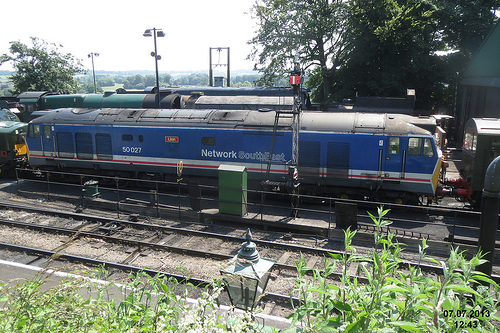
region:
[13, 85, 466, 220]
trains on the tracks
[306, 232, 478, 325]
green leaves on a tree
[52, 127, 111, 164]
windows of a train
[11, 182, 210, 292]
tracks of a train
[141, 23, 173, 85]
lights above a train station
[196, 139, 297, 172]
name of train on side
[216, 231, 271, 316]
lamp light by the tracks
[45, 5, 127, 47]
hazy sky in the distance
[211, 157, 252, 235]
electric box on the tracks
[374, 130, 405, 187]
door of a train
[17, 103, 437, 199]
a blue train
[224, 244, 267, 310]
a lamp post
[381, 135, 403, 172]
a door on the train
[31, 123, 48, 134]
a window on the train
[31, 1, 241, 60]
the sky above the train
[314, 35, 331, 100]
the trunk on the tree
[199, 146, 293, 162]
writing on the train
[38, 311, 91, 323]
Part of the green trees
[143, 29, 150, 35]
Part of the streetlight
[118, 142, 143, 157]
Numbers on the train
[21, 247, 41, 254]
Part of the train tracks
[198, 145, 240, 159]
Letters on the train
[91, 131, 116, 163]
A window on the train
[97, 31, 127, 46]
Part of the sky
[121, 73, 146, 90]
A tree in distance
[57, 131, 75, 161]
window on the train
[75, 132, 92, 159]
window on the train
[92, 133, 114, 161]
window on the train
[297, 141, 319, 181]
window on the train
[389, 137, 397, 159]
window on the train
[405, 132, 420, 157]
window on the train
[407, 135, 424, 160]
window on the train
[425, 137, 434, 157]
window on the train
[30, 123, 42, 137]
window on the train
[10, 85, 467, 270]
The train is blue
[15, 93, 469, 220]
The train has a white stripe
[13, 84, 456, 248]
The train has a red stripe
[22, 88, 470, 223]
The train has numbers on it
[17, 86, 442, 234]
The train has white letters on it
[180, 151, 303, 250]
The green box is on the tracks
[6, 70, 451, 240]
The train is on the tracks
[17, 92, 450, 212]
the train is color blue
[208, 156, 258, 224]
the box is color green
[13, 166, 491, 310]
the rails on a train station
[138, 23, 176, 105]
a light behind a pole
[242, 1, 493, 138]
trees behind a pole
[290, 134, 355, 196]
two doors of a train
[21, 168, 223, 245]
a fence next a rail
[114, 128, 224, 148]
windows on side the train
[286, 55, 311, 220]
a pole on front a train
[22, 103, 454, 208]
blue colored train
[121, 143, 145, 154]
number 50027 on the train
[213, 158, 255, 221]
green metal box near the train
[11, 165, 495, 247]
metal rail near the train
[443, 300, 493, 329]
date marked on the picture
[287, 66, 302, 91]
red light above the train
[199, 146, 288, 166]
train line's name on a train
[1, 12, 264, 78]
clear white sky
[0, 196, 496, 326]
empty train tracks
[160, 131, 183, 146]
red sign on the side of a train